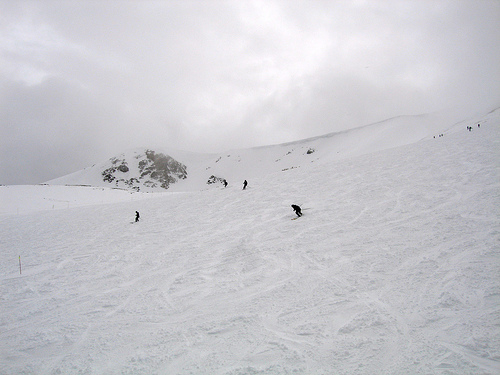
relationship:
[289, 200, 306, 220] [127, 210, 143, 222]
person in front of people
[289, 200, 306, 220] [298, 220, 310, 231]
person skiing down white snow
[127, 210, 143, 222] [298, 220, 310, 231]
people skiing down white snow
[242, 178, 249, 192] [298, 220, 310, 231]
person skiing down white snow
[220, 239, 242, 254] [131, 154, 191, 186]
snow covered mountain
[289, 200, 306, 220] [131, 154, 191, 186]
person ski down mountain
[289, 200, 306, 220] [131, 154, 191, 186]
person has skied down mountain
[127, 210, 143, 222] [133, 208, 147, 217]
people wearing black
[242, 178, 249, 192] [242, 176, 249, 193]
person wearing black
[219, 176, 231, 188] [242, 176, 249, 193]
skier wearing black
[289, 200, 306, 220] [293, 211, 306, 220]
person using skis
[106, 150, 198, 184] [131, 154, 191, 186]
outcrop on mountain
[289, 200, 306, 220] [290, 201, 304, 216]
person wearing black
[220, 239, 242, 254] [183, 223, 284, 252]
snow on field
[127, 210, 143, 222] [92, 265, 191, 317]
people going down hill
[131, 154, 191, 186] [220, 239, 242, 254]
mountain not covered in snow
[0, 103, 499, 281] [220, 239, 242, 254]
mountain covered in snow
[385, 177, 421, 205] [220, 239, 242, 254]
tracks in snow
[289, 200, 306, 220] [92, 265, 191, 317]
person on hill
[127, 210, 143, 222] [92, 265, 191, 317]
people on hill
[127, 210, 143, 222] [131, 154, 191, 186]
people snowboarding on mountain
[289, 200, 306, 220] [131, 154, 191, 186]
person skiing on mountain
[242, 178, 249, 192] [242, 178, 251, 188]
person in distance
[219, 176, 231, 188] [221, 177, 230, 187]
skier in distance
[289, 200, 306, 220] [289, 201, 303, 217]
person participating in outdoors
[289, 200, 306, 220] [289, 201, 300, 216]
person exercising outdoors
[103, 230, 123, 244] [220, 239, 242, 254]
paths carved in snow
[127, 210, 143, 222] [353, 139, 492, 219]
people in mountains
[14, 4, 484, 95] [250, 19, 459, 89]
sky in background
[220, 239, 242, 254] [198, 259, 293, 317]
snow on ground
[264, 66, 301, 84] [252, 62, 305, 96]
sunlight peking out behind clouds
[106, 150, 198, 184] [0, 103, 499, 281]
hill on mountain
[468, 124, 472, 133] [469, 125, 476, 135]
skier in distance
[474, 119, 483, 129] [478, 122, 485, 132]
skier in distance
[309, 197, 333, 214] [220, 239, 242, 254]
track in snow